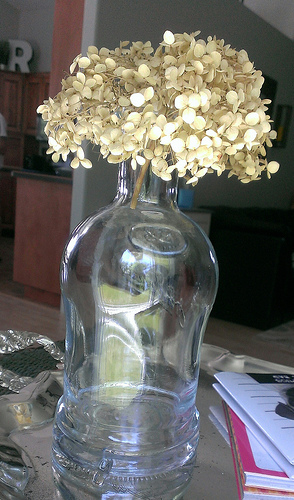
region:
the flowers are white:
[53, 77, 257, 194]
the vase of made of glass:
[68, 304, 251, 493]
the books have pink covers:
[218, 404, 285, 493]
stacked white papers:
[223, 382, 283, 462]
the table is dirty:
[25, 454, 59, 497]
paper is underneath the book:
[204, 404, 259, 493]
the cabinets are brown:
[19, 194, 92, 266]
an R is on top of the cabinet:
[7, 35, 54, 87]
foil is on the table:
[8, 326, 158, 455]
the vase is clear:
[86, 232, 196, 431]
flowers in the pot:
[51, 37, 268, 184]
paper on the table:
[213, 375, 286, 448]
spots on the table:
[190, 432, 221, 491]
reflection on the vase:
[105, 427, 138, 482]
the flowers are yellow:
[167, 89, 209, 146]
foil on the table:
[7, 327, 49, 395]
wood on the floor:
[250, 337, 285, 356]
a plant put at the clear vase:
[24, 49, 240, 489]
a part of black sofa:
[219, 190, 292, 328]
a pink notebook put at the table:
[216, 390, 292, 498]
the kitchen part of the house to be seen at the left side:
[1, 108, 69, 311]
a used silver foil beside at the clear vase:
[4, 324, 73, 404]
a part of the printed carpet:
[249, 320, 293, 360]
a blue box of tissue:
[175, 183, 206, 210]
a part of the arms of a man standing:
[0, 105, 23, 163]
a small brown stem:
[126, 167, 152, 219]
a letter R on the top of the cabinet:
[9, 33, 39, 82]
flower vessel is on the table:
[78, 228, 217, 469]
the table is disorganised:
[24, 328, 289, 473]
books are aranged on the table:
[234, 385, 276, 493]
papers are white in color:
[247, 392, 289, 448]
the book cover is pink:
[228, 429, 248, 481]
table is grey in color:
[196, 455, 225, 495]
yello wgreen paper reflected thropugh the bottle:
[98, 288, 155, 398]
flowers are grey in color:
[125, 67, 236, 155]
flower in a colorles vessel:
[73, 75, 234, 216]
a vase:
[70, 205, 209, 399]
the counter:
[199, 470, 225, 495]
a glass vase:
[76, 215, 209, 446]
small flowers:
[69, 43, 263, 173]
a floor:
[15, 306, 49, 332]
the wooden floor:
[237, 335, 260, 349]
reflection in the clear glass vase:
[90, 294, 159, 357]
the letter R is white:
[7, 36, 32, 69]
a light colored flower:
[17, 28, 286, 206]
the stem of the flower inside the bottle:
[125, 163, 156, 211]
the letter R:
[6, 34, 38, 82]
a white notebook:
[210, 336, 292, 480]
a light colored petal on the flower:
[160, 24, 173, 42]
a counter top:
[3, 137, 81, 197]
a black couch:
[196, 191, 292, 326]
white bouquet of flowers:
[36, 28, 282, 191]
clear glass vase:
[39, 152, 222, 492]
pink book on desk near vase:
[218, 379, 288, 490]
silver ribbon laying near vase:
[5, 307, 69, 395]